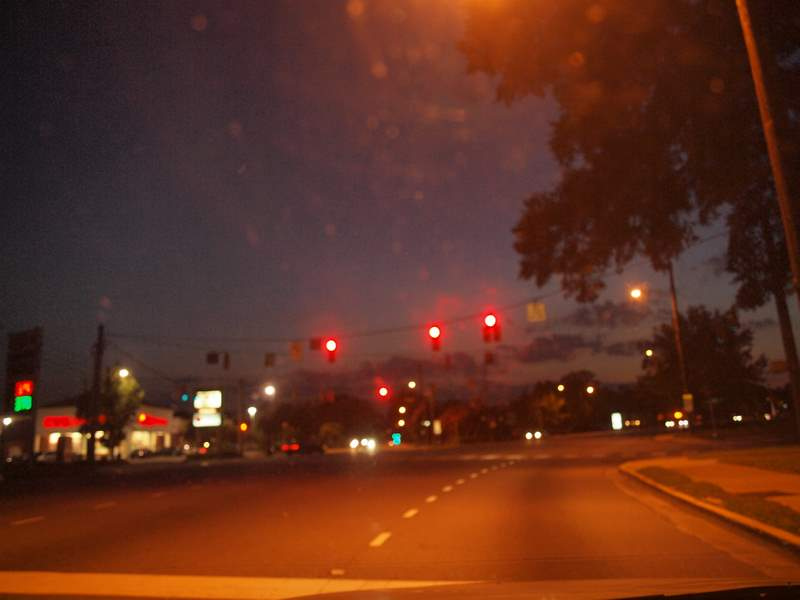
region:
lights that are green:
[10, 393, 39, 412]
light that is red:
[8, 376, 35, 400]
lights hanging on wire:
[6, 276, 755, 405]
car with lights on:
[340, 434, 380, 455]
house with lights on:
[22, 389, 190, 467]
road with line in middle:
[8, 421, 794, 589]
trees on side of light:
[506, 104, 791, 441]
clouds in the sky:
[12, 4, 786, 385]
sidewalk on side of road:
[11, 424, 793, 593]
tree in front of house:
[21, 356, 198, 468]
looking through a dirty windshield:
[2, 0, 795, 582]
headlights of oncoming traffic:
[345, 412, 743, 452]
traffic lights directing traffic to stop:
[96, 309, 686, 369]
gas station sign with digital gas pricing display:
[2, 331, 45, 485]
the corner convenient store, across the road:
[35, 401, 189, 460]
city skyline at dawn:
[8, 9, 789, 454]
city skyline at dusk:
[2, 1, 795, 420]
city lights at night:
[2, 260, 795, 477]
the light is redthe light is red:
[470, 303, 507, 345]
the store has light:
[29, 405, 191, 463]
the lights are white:
[239, 372, 287, 429]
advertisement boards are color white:
[184, 381, 227, 439]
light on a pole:
[617, 270, 683, 328]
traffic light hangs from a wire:
[310, 331, 352, 368]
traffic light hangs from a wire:
[417, 310, 453, 361]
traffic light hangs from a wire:
[474, 301, 504, 345]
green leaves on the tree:
[605, 202, 623, 238]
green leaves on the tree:
[544, 220, 571, 320]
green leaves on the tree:
[752, 241, 790, 327]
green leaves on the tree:
[688, 102, 752, 179]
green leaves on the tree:
[628, 47, 733, 138]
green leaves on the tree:
[683, 38, 774, 131]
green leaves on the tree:
[491, 26, 577, 112]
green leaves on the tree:
[708, 344, 749, 405]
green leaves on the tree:
[690, 294, 726, 374]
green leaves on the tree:
[612, 344, 676, 440]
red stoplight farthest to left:
[317, 332, 339, 360]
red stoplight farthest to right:
[480, 308, 507, 340]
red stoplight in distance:
[374, 381, 393, 400]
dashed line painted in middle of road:
[325, 455, 519, 583]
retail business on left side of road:
[35, 400, 189, 453]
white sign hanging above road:
[525, 300, 547, 322]